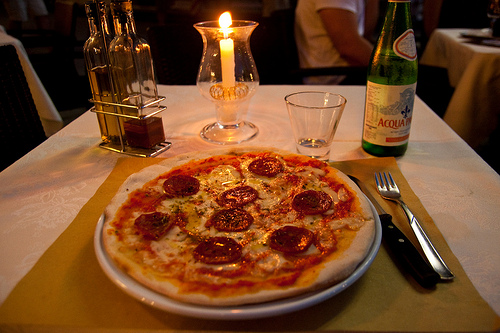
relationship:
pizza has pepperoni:
[102, 143, 377, 307] [248, 157, 283, 177]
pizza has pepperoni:
[102, 143, 377, 307] [292, 190, 333, 215]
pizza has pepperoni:
[102, 143, 377, 307] [267, 225, 316, 254]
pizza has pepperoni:
[102, 143, 377, 307] [191, 235, 244, 265]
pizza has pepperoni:
[102, 143, 377, 307] [161, 173, 201, 200]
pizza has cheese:
[102, 143, 377, 307] [127, 154, 366, 272]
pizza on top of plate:
[102, 143, 377, 307] [93, 192, 384, 320]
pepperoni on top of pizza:
[248, 157, 283, 177] [102, 143, 377, 307]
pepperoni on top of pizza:
[292, 190, 333, 215] [102, 143, 377, 307]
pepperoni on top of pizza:
[267, 225, 316, 254] [102, 143, 377, 307]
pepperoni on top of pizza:
[191, 235, 244, 265] [102, 143, 377, 307]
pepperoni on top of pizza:
[161, 173, 201, 200] [102, 143, 377, 307]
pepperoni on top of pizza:
[209, 207, 254, 232] [102, 143, 377, 307]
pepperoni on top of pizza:
[220, 185, 260, 207] [102, 143, 377, 307]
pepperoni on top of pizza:
[132, 211, 176, 241] [102, 143, 377, 307]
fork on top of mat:
[372, 169, 455, 281] [0, 155, 499, 332]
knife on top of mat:
[347, 174, 441, 286] [0, 155, 499, 332]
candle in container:
[216, 11, 238, 123] [192, 19, 261, 145]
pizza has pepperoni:
[102, 143, 377, 307] [132, 211, 176, 241]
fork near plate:
[372, 169, 455, 281] [93, 192, 384, 320]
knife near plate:
[347, 174, 441, 286] [93, 192, 384, 320]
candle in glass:
[216, 11, 238, 123] [192, 19, 261, 145]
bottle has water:
[361, 0, 420, 156] [362, 48, 418, 156]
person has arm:
[293, 0, 373, 85] [319, 9, 375, 70]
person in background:
[293, 0, 373, 85] [0, 1, 499, 84]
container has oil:
[81, 1, 129, 145] [85, 67, 129, 146]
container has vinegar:
[108, 2, 167, 149] [124, 115, 168, 149]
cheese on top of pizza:
[127, 154, 366, 272] [102, 143, 377, 307]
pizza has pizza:
[102, 143, 377, 307] [102, 143, 377, 307]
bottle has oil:
[361, 0, 420, 156] [85, 67, 129, 146]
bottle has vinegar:
[361, 0, 420, 156] [124, 115, 168, 149]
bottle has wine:
[361, 0, 420, 156] [362, 48, 418, 156]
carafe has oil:
[81, 1, 129, 145] [85, 67, 129, 146]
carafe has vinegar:
[108, 2, 167, 149] [124, 115, 168, 149]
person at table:
[293, 0, 373, 85] [419, 25, 499, 152]